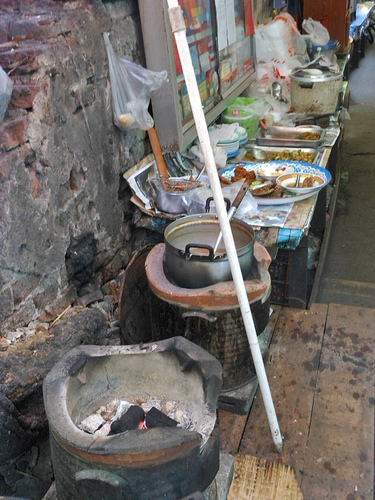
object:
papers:
[215, 0, 237, 52]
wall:
[0, 0, 154, 500]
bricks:
[13, 273, 39, 308]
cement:
[0, 0, 146, 275]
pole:
[167, 0, 284, 454]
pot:
[290, 67, 344, 117]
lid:
[289, 63, 343, 83]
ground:
[262, 128, 321, 138]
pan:
[256, 125, 326, 148]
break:
[65, 234, 96, 289]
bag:
[102, 34, 169, 130]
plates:
[206, 129, 241, 159]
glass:
[173, 0, 254, 128]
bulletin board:
[139, 1, 257, 153]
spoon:
[213, 168, 256, 253]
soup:
[189, 248, 226, 256]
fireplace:
[42, 335, 224, 500]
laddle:
[209, 172, 252, 254]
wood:
[300, 301, 375, 500]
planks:
[225, 303, 332, 500]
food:
[231, 165, 247, 181]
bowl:
[276, 172, 325, 190]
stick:
[163, 0, 284, 453]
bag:
[255, 13, 307, 102]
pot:
[164, 197, 256, 290]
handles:
[205, 196, 231, 212]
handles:
[184, 243, 215, 261]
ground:
[228, 40, 375, 500]